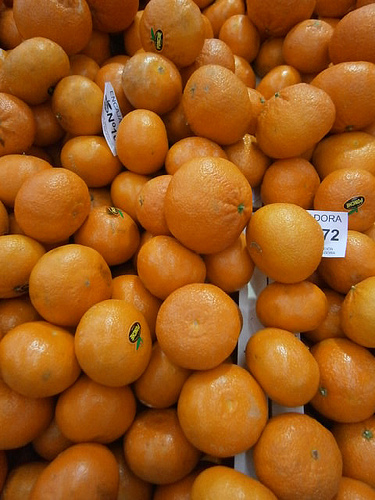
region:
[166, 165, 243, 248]
orange's skin is rough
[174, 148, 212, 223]
orange's skin is textured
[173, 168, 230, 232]
orange's skin is textured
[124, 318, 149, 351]
sticker on the orange's skin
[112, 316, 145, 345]
sticker on the orange's skin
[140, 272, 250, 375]
orange in a cart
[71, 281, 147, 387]
orange in a cart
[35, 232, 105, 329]
orange in a cart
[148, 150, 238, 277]
orange in a cart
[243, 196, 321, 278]
orange in a cart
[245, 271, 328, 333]
orange in a cart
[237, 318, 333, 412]
orange in a cart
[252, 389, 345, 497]
orange in a cart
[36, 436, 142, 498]
orange in a cart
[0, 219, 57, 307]
orange in a cart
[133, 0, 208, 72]
The orange is unpeeled.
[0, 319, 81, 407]
The orange is unpeeled.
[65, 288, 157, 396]
The orange is unpeeled.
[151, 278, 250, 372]
The orange is unpeeled.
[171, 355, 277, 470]
The orange is unpeeled.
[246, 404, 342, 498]
The orange is unpeeled.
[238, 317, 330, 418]
The orange is unpeeled.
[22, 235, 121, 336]
The orange is unpeeled.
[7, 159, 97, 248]
The orange is unpeeled.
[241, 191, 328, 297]
The orange is unpeeled.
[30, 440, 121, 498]
A orange in a bin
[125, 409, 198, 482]
An orange in the bin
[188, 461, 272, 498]
An orange in the bin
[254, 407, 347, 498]
An orange in the bin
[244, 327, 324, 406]
An orange in the bin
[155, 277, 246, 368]
An orange in the bin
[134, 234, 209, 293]
An orange in the bin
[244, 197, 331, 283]
An orange in the bin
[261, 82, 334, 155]
An orange in the bin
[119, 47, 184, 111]
An orange in the bin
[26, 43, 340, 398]
this is at a fruit stand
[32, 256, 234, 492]
these are oranges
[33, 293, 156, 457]
the color of these fruits is orange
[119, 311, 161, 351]
there are stickers on the oranges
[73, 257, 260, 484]
these oranges are for sale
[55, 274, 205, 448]
these are a bunch of oranges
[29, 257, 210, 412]
the oranges are round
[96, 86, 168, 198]
this is a price tag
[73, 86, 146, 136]
the price tag is white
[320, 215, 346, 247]
the writing is black